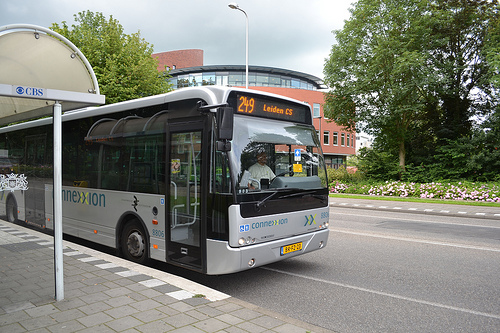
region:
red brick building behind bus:
[145, 46, 357, 172]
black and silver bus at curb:
[0, 80, 330, 280]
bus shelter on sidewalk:
[0, 25, 102, 297]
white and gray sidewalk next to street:
[0, 215, 325, 327]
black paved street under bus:
[192, 205, 493, 330]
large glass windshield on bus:
[215, 110, 325, 190]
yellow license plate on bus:
[277, 235, 307, 250]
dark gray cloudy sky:
[0, 0, 496, 145]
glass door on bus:
[165, 115, 210, 267]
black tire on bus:
[113, 213, 145, 258]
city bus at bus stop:
[1, 86, 328, 280]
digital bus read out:
[228, 89, 309, 126]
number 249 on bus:
[234, 93, 258, 115]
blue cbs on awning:
[13, 83, 47, 98]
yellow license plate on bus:
[276, 240, 303, 257]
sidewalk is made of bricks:
[0, 215, 324, 332]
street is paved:
[193, 206, 498, 331]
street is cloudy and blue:
[1, 1, 499, 131]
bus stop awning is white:
[0, 23, 105, 301]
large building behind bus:
[143, 47, 359, 179]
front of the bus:
[208, 87, 327, 261]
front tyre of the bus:
[126, 212, 167, 264]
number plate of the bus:
[270, 233, 325, 275]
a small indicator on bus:
[296, 212, 321, 235]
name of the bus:
[231, 210, 300, 242]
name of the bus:
[33, 164, 123, 222]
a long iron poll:
[40, 100, 80, 331]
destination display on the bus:
[232, 88, 340, 135]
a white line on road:
[315, 247, 495, 321]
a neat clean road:
[328, 193, 479, 327]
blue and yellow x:
[80, 187, 92, 207]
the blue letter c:
[22, 81, 33, 101]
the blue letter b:
[29, 80, 39, 102]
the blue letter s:
[33, 84, 50, 101]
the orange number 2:
[233, 96, 249, 114]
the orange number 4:
[239, 94, 254, 116]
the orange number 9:
[243, 86, 255, 113]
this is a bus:
[1, 59, 351, 278]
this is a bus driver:
[239, 138, 279, 185]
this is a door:
[153, 105, 236, 282]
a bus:
[122, 133, 288, 324]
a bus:
[196, 125, 346, 313]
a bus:
[162, 137, 247, 255]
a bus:
[191, 171, 271, 286]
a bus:
[185, 128, 292, 268]